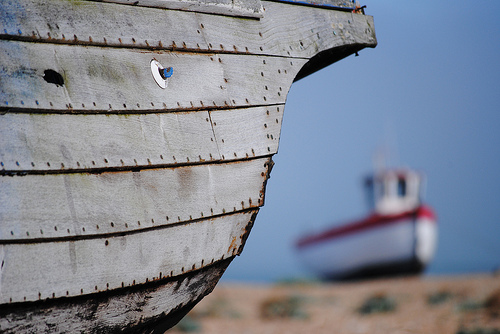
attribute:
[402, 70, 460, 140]
sky — blue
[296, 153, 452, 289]
boat — red, white , blue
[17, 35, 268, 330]
wood panels — wood 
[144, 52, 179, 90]
hole — patched up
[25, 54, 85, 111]
hole — small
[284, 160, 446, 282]
boat — small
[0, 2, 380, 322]
boat — older, distressed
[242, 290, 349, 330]
sand — rocky